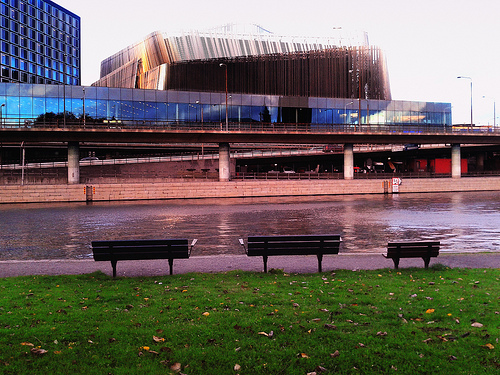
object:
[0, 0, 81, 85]
building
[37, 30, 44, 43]
windows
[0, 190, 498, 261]
water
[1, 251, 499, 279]
sidewalk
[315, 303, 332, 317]
leaves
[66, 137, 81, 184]
support pillar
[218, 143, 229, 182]
support pillar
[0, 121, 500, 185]
bridge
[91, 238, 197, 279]
bench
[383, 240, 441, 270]
bench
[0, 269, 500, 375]
grass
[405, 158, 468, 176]
truck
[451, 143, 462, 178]
pillar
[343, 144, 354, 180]
pillar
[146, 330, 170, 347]
leaves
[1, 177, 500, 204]
wall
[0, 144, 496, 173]
ramp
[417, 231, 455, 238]
ripple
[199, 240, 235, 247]
ripple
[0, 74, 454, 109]
rooftop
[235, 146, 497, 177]
garage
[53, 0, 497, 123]
sky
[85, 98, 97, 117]
window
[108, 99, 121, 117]
window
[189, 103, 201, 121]
window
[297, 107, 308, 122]
window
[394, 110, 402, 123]
window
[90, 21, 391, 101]
design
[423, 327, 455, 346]
leaves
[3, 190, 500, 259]
lake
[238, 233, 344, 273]
bench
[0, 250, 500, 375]
ground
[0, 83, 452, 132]
wall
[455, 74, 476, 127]
lights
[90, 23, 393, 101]
building